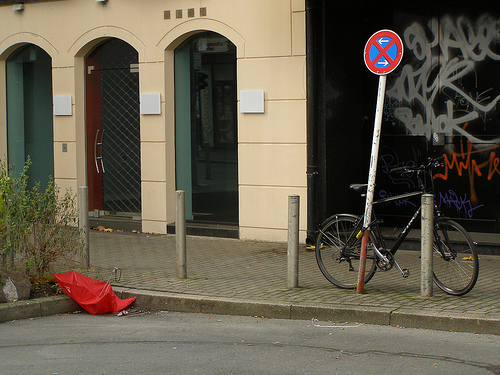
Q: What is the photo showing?
A: It is showing a sidewalk.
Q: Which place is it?
A: It is a sidewalk.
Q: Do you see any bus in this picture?
A: No, there are no buses.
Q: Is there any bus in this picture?
A: No, there are no buses.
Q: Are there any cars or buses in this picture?
A: No, there are no buses or cars.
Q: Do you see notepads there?
A: No, there are no notepads.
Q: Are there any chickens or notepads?
A: No, there are no notepads or chickens.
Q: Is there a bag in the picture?
A: No, there are no bags.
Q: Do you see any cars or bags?
A: No, there are no bags or cars.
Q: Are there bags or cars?
A: No, there are no bags or cars.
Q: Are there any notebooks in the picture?
A: No, there are no notebooks.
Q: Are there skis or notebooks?
A: No, there are no notebooks or skis.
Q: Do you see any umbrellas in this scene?
A: Yes, there is an umbrella.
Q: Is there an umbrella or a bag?
A: Yes, there is an umbrella.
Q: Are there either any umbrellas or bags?
A: Yes, there is an umbrella.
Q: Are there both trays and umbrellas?
A: No, there is an umbrella but no trays.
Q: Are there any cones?
A: No, there are no cones.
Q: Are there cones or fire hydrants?
A: No, there are no cones or fire hydrants.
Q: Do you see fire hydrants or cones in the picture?
A: No, there are no cones or fire hydrants.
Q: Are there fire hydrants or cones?
A: No, there are no cones or fire hydrants.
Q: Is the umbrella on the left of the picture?
A: Yes, the umbrella is on the left of the image.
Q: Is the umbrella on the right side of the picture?
A: No, the umbrella is on the left of the image.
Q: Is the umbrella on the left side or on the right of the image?
A: The umbrella is on the left of the image.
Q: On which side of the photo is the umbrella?
A: The umbrella is on the left of the image.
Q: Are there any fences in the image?
A: No, there are no fences.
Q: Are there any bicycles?
A: Yes, there is a bicycle.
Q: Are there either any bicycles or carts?
A: Yes, there is a bicycle.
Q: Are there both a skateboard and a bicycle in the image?
A: No, there is a bicycle but no skateboards.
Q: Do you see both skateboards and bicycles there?
A: No, there is a bicycle but no skateboards.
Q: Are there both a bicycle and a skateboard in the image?
A: No, there is a bicycle but no skateboards.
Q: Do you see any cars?
A: No, there are no cars.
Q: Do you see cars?
A: No, there are no cars.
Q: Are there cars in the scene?
A: No, there are no cars.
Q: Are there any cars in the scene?
A: No, there are no cars.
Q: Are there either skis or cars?
A: No, there are no cars or skis.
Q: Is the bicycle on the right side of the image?
A: Yes, the bicycle is on the right of the image.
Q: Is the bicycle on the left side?
A: No, the bicycle is on the right of the image.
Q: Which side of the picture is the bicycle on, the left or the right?
A: The bicycle is on the right of the image.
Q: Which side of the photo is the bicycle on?
A: The bicycle is on the right of the image.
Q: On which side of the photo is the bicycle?
A: The bicycle is on the right of the image.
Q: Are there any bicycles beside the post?
A: Yes, there is a bicycle beside the post.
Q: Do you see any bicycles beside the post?
A: Yes, there is a bicycle beside the post.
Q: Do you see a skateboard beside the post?
A: No, there is a bicycle beside the post.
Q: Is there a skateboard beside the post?
A: No, there is a bicycle beside the post.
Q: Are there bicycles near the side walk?
A: Yes, there is a bicycle near the side walk.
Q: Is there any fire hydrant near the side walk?
A: No, there is a bicycle near the side walk.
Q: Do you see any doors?
A: Yes, there is a door.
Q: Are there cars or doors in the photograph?
A: Yes, there is a door.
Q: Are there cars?
A: No, there are no cars.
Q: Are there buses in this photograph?
A: No, there are no buses.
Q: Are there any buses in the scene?
A: No, there are no buses.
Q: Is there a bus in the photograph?
A: No, there are no buses.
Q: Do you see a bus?
A: No, there are no buses.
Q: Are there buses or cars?
A: No, there are no buses or cars.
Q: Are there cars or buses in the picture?
A: No, there are no buses or cars.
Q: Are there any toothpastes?
A: No, there are no toothpastes.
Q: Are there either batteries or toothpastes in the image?
A: No, there are no toothpastes or batteries.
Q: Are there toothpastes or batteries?
A: No, there are no toothpastes or batteries.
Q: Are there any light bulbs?
A: No, there are no light bulbs.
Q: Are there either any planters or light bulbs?
A: No, there are no light bulbs or planters.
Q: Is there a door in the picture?
A: Yes, there is a door.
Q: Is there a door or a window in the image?
A: Yes, there is a door.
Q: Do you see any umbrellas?
A: Yes, there is an umbrella.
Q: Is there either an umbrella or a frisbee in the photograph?
A: Yes, there is an umbrella.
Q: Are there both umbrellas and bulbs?
A: No, there is an umbrella but no light bulbs.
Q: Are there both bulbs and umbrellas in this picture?
A: No, there is an umbrella but no light bulbs.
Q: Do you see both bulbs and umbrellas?
A: No, there is an umbrella but no light bulbs.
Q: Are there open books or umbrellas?
A: Yes, there is an open umbrella.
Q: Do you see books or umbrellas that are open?
A: Yes, the umbrella is open.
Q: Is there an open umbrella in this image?
A: Yes, there is an open umbrella.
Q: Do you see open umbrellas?
A: Yes, there is an open umbrella.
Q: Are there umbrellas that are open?
A: Yes, there is an umbrella that is open.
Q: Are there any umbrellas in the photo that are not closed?
A: Yes, there is a open umbrella.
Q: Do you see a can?
A: No, there are no cans.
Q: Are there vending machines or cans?
A: No, there are no cans or vending machines.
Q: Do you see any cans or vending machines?
A: No, there are no cans or vending machines.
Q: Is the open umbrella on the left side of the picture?
A: Yes, the umbrella is on the left of the image.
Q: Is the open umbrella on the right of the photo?
A: No, the umbrella is on the left of the image.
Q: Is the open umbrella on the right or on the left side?
A: The umbrella is on the left of the image.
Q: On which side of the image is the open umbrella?
A: The umbrella is on the left of the image.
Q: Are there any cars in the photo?
A: No, there are no cars.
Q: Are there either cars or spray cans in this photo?
A: No, there are no cars or spray cans.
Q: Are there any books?
A: No, there are no books.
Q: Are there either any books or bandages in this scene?
A: No, there are no books or bandages.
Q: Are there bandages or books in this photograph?
A: No, there are no books or bandages.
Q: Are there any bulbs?
A: No, there are no bulbs.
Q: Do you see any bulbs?
A: No, there are no bulbs.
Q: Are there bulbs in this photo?
A: No, there are no bulbs.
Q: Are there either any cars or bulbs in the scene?
A: No, there are no bulbs or cars.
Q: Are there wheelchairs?
A: No, there are no wheelchairs.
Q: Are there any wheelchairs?
A: No, there are no wheelchairs.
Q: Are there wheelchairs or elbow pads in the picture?
A: No, there are no wheelchairs or elbow pads.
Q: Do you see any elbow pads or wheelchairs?
A: No, there are no wheelchairs or elbow pads.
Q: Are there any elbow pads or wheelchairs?
A: No, there are no wheelchairs or elbow pads.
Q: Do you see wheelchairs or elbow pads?
A: No, there are no wheelchairs or elbow pads.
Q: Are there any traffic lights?
A: No, there are no traffic lights.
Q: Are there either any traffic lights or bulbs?
A: No, there are no traffic lights or bulbs.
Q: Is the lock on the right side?
A: Yes, the lock is on the right of the image.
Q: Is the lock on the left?
A: No, the lock is on the right of the image.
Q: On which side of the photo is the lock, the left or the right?
A: The lock is on the right of the image.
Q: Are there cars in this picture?
A: No, there are no cars.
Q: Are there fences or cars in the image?
A: No, there are no cars or fences.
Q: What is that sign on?
A: The sign is on the pole.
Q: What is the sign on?
A: The sign is on the pole.